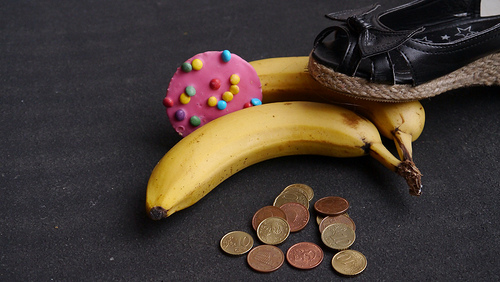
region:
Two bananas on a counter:
[138, 44, 430, 216]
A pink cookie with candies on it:
[158, 42, 260, 129]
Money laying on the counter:
[218, 183, 369, 278]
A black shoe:
[303, 6, 483, 98]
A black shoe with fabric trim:
[377, 58, 499, 93]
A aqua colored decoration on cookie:
[216, 42, 233, 63]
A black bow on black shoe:
[326, 6, 423, 67]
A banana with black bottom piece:
[116, 115, 443, 226]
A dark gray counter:
[56, 60, 116, 227]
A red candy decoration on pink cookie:
[205, 72, 221, 90]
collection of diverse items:
[128, 10, 458, 270]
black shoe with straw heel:
[310, 0, 495, 90]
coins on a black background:
[220, 181, 370, 271]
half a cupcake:
[165, 47, 260, 92]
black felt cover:
[11, 50, 126, 260]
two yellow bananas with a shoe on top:
[280, 15, 446, 165]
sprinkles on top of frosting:
[201, 70, 236, 105]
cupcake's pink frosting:
[206, 60, 243, 66]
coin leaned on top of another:
[312, 190, 352, 220]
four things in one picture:
[133, 7, 458, 273]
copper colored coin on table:
[279, 230, 332, 280]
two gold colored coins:
[327, 228, 361, 278]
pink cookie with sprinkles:
[167, 48, 269, 119]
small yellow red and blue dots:
[163, 53, 256, 104]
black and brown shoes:
[335, 10, 470, 102]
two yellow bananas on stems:
[240, 75, 439, 202]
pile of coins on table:
[239, 180, 376, 270]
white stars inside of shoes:
[369, 8, 479, 70]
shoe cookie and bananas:
[157, 4, 473, 178]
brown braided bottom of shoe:
[255, 55, 499, 97]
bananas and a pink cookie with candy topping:
[145, 39, 298, 175]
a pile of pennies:
[221, 177, 381, 276]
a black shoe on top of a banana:
[300, 7, 497, 101]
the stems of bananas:
[373, 125, 435, 190]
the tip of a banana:
[144, 192, 176, 227]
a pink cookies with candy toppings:
[159, 42, 261, 114]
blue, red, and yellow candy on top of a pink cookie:
[160, 49, 264, 115]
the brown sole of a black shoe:
[306, 49, 498, 104]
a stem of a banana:
[396, 125, 426, 196]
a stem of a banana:
[366, 133, 408, 193]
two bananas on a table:
[136, 39, 430, 224]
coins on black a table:
[206, 165, 373, 277]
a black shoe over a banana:
[302, 5, 497, 140]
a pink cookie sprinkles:
[156, 38, 264, 151]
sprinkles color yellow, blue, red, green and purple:
[154, 43, 268, 148]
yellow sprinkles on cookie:
[221, 73, 242, 98]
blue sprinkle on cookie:
[211, 46, 236, 61]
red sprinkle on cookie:
[203, 73, 228, 93]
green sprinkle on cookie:
[184, 108, 204, 130]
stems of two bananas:
[379, 132, 436, 200]